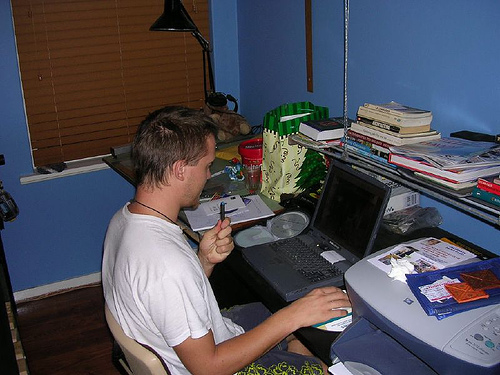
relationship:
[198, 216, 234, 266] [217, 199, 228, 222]
hand holding pen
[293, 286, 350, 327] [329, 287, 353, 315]
hand on top of mouse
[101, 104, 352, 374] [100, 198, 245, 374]
man wearing shirt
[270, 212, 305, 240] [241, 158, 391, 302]
cd next to laptop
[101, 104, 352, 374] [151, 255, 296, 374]
man has arm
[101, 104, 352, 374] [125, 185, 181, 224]
man has eck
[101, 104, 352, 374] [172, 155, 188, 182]
man has ear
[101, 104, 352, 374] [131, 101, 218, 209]
man has head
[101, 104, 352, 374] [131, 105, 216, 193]
man has hair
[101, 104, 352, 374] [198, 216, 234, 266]
man has hand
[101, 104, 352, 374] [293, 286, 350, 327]
man has hand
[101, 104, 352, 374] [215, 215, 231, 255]
man has figers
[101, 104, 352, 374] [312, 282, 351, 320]
man has figers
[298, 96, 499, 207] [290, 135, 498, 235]
books stacked o book shelf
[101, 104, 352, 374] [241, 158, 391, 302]
man sitting i frot of laptop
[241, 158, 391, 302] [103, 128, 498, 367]
laptop o top of desk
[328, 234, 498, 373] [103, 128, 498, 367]
printer o top of desk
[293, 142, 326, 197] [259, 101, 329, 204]
christmas tree o frot of bag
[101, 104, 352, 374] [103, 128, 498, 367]
man sitting at desk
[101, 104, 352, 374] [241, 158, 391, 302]
man using laptop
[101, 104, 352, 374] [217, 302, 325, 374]
man wearing shorts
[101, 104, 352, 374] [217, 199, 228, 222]
man holding pen